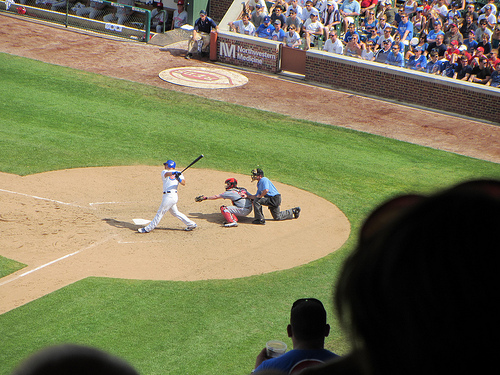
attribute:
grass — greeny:
[44, 100, 82, 141]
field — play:
[66, 43, 98, 63]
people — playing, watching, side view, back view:
[154, 161, 274, 238]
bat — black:
[177, 142, 206, 170]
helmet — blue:
[162, 160, 174, 170]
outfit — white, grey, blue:
[145, 183, 191, 210]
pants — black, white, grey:
[258, 193, 278, 225]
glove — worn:
[174, 171, 186, 184]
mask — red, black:
[221, 176, 233, 188]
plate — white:
[134, 219, 147, 229]